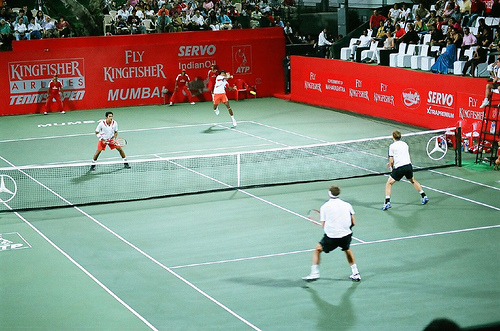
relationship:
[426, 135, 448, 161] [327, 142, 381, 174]
logo on net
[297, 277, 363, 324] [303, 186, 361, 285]
shadow of man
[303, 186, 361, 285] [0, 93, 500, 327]
man on court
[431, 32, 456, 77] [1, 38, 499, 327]
spectator watching tennis match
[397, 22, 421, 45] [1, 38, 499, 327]
spectator watching tennis match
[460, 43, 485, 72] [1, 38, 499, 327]
spectator watching tennis match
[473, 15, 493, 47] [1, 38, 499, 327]
spectator watching tennis match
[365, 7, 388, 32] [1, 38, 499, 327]
spectator watching tennis match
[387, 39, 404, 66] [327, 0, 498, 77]
chair in stands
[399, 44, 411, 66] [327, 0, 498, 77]
chair in stands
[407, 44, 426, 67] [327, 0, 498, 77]
chair in stands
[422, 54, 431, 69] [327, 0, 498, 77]
chair in stands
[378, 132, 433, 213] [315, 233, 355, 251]
man wearing black shorts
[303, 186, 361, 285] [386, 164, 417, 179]
man wearing black shorts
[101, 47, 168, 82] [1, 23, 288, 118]
advertisement on wall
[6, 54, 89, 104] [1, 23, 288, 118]
advertisement on wall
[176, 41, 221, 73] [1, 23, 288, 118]
advertisement on wall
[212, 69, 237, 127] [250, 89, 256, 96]
man hitting ball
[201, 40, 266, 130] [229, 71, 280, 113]
man returning ball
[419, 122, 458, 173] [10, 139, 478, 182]
logo on net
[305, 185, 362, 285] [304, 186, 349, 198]
man wearing headband